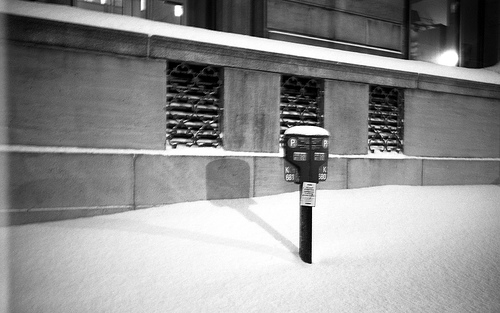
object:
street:
[0, 228, 499, 311]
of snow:
[165, 211, 292, 266]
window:
[163, 60, 225, 150]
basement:
[86, 53, 495, 150]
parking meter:
[279, 124, 333, 263]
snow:
[281, 125, 332, 135]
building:
[0, 0, 499, 227]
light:
[432, 47, 462, 69]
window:
[407, 0, 464, 67]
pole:
[298, 183, 316, 262]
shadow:
[203, 158, 299, 256]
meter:
[298, 181, 319, 208]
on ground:
[0, 264, 499, 312]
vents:
[364, 83, 411, 158]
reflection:
[417, 46, 457, 65]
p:
[288, 137, 297, 148]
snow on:
[367, 150, 414, 159]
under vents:
[154, 146, 411, 164]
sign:
[281, 123, 332, 266]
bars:
[456, 6, 488, 70]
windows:
[403, 0, 489, 61]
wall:
[0, 39, 151, 228]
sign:
[279, 123, 336, 185]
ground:
[0, 221, 499, 312]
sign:
[317, 165, 330, 182]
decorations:
[129, 1, 264, 32]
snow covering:
[255, 265, 377, 282]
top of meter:
[283, 123, 333, 136]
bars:
[166, 64, 225, 147]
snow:
[167, 141, 226, 156]